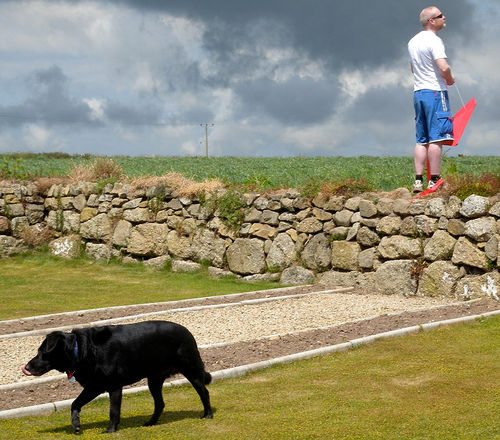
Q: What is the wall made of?
A: Stones.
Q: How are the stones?
A: Piled.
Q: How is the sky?
A: Cloudy.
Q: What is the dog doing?
A: Walking.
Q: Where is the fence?
A: Next to yard.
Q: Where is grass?
A: The field.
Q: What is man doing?
A: Standing.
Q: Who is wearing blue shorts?
A: The man.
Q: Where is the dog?
A: On the field.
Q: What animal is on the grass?
A: Dog.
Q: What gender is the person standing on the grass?
A: Male.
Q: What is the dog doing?
A: Walking.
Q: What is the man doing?
A: Standing.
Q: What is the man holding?
A: A kite.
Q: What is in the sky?
A: Clouds.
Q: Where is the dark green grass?
A: Above the stone wall.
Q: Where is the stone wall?
A: Beneath the man.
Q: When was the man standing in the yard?
A: During daylight hours.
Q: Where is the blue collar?
A: On the black dog.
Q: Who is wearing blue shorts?
A: The man holding a kite.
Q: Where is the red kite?
A: With the man in a white shirt.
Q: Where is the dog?
A: In the grass.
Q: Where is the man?
A: Standing above the rocky ledge.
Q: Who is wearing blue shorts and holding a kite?
A: The man in the white shirt.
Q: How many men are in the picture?
A: One.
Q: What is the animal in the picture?
A: Dog.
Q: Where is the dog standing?
A: Grass.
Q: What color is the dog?
A: Black.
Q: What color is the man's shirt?
A: White.